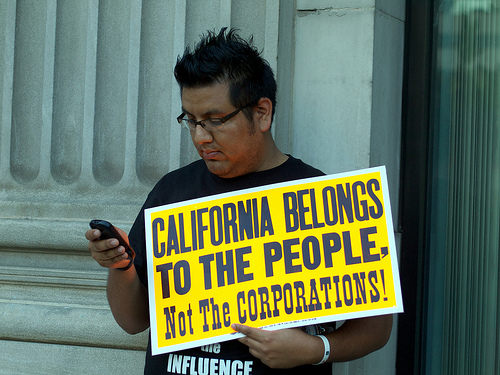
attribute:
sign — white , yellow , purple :
[92, 164, 425, 361]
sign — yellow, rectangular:
[134, 159, 406, 360]